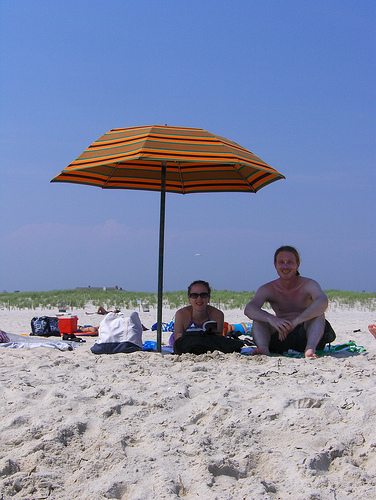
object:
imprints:
[101, 480, 126, 500]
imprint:
[59, 429, 74, 447]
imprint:
[103, 481, 130, 500]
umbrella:
[49, 122, 286, 354]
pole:
[156, 161, 167, 353]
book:
[186, 320, 217, 332]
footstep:
[103, 396, 140, 420]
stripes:
[147, 133, 197, 141]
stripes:
[147, 145, 241, 153]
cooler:
[57, 315, 79, 335]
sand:
[243, 411, 307, 465]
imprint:
[58, 421, 89, 448]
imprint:
[207, 457, 248, 481]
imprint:
[309, 445, 350, 483]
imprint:
[284, 393, 332, 409]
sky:
[0, 0, 376, 125]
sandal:
[61, 332, 86, 343]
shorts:
[253, 319, 328, 355]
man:
[244, 245, 329, 358]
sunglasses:
[188, 292, 211, 299]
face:
[189, 282, 209, 312]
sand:
[65, 373, 101, 401]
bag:
[90, 310, 143, 355]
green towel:
[330, 341, 365, 354]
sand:
[323, 356, 363, 383]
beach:
[0, 364, 376, 500]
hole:
[205, 459, 247, 489]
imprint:
[2, 468, 61, 500]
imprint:
[19, 381, 36, 388]